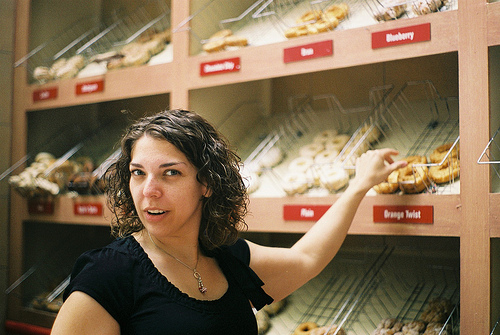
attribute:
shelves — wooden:
[15, 5, 471, 329]